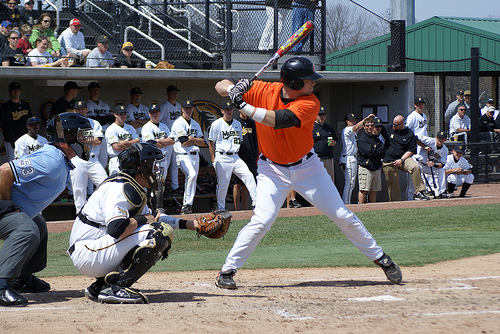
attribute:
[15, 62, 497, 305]
game — baseball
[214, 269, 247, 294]
foot — planted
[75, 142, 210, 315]
man — crouching, crouched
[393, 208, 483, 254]
grass — green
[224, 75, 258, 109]
gloves — dark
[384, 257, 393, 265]
logo — white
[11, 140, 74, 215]
jersey — blue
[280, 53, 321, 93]
helmet — shiny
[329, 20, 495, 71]
roof — green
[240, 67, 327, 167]
jersey — orange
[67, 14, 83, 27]
cap — red, white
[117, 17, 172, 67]
railing — silver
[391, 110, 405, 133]
head — bald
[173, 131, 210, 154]
arms — crossed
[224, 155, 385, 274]
pants — white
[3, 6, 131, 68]
crowd — small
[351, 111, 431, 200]
coaches — talking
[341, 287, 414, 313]
plate — white, home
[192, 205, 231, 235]
glove — brown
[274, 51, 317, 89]
helmet — black